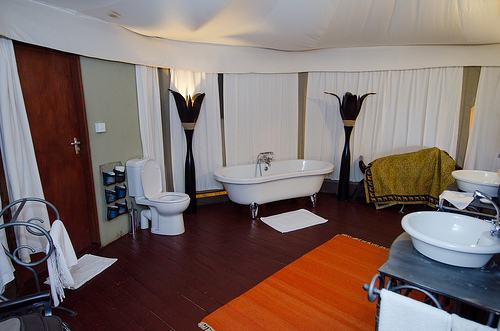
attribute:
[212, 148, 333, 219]
tub — white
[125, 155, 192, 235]
toilet — on a wooden floor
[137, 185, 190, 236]
toilet bowl — white 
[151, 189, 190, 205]
toilet seat — white 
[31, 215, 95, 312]
towel — white 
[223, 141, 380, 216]
tub — white 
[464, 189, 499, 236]
faucet — chrome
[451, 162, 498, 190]
sink — white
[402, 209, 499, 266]
sink — white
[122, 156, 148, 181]
porcelain — white 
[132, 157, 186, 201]
tank — white 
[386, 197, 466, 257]
sink — white